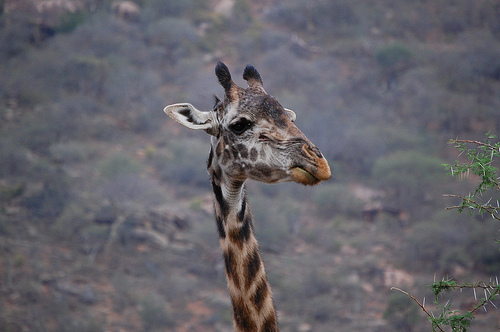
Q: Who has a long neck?
A: The giraffe.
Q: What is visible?
A: Tree branches.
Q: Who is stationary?
A: The giraffe.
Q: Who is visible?
A: The giraffe.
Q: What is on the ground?
A: Grass.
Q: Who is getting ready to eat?
A: The giraffe.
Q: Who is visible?
A: The giraffe.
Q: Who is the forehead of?
A: A giraffe.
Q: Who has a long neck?
A: A giraffe.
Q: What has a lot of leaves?
A: A tree.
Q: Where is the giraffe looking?
A: To the right.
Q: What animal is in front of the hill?
A: Giraffe.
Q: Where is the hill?
A: Behind the giraffe.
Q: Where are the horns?
A: On the head.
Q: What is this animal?
A: Giraffe.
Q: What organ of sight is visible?
A: The right eye of the giraffe.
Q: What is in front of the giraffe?
A: The tree branch.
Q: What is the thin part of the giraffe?
A: Neck.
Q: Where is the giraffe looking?
A: Toward the tree.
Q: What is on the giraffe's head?
A: Horns.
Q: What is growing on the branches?
A: Leaves.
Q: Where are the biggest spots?
A: On the neck.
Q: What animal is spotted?
A: Giraffe.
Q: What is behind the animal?
A: The ground.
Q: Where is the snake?
A: No snake.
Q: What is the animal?
A: A giraffe.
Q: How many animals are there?
A: One.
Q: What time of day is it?
A: Day time.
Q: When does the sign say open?
A: No sign.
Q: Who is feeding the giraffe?
A: No one.